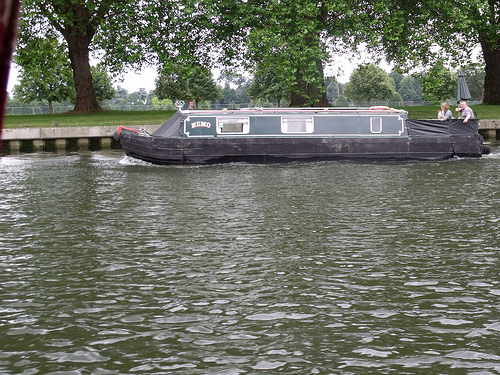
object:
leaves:
[273, 35, 277, 42]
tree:
[246, 0, 335, 108]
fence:
[3, 105, 181, 112]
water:
[0, 151, 498, 371]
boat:
[110, 105, 490, 165]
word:
[207, 122, 212, 129]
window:
[281, 115, 314, 134]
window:
[370, 117, 383, 133]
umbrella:
[456, 70, 471, 104]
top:
[458, 69, 464, 77]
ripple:
[90, 166, 500, 315]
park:
[0, 79, 484, 113]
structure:
[2, 128, 26, 151]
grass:
[6, 110, 159, 124]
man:
[455, 99, 475, 123]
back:
[407, 119, 480, 155]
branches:
[303, 61, 312, 84]